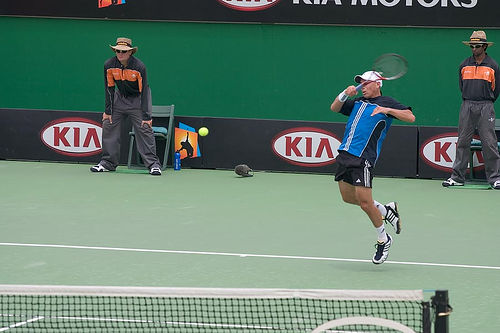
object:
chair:
[127, 104, 177, 171]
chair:
[466, 138, 496, 184]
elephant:
[90, 37, 162, 175]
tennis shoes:
[372, 232, 394, 264]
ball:
[198, 127, 208, 136]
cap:
[354, 71, 383, 89]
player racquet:
[341, 53, 411, 101]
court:
[0, 0, 498, 333]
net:
[1, 283, 435, 330]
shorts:
[334, 153, 375, 188]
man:
[442, 31, 500, 190]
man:
[90, 37, 162, 175]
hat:
[462, 30, 493, 47]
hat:
[109, 38, 138, 55]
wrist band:
[338, 90, 349, 102]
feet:
[371, 232, 393, 264]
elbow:
[405, 109, 416, 123]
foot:
[387, 202, 401, 232]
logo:
[272, 127, 342, 167]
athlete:
[329, 71, 416, 265]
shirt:
[338, 96, 412, 166]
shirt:
[458, 52, 498, 101]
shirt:
[103, 55, 152, 121]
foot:
[488, 179, 499, 190]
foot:
[442, 178, 465, 187]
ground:
[0, 159, 499, 333]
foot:
[149, 168, 162, 176]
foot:
[90, 163, 116, 172]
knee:
[135, 123, 153, 134]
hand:
[102, 112, 113, 124]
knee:
[102, 120, 114, 128]